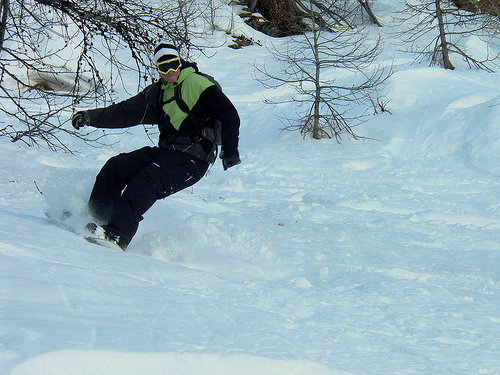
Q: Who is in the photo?
A: A man.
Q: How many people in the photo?
A: One.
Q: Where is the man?
A: The mountain.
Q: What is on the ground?
A: Snow.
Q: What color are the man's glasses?
A: Yellow.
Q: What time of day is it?
A: Day time.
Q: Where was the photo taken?
A: In the mountains.